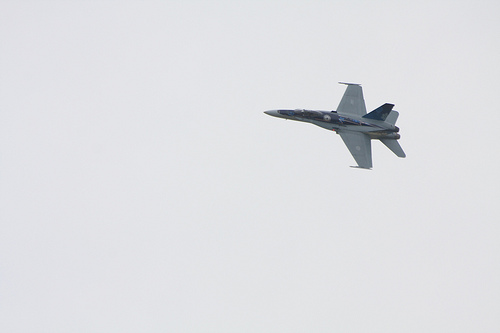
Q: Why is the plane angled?
A: It is turning.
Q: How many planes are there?
A: One.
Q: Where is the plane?
A: In the sky.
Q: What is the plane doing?
A: Flying.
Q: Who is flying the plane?
A: A pilot.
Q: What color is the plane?
A: Gray.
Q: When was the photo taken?
A: Daytime.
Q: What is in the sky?
A: Clouds.